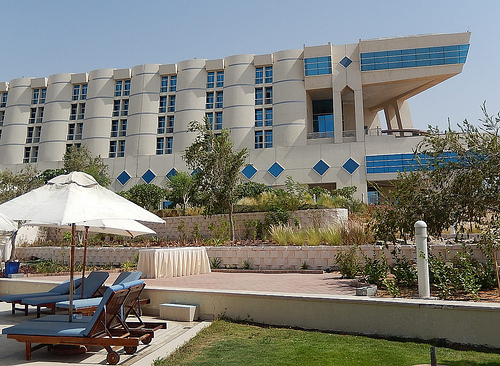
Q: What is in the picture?
A: A building.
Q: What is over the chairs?
A: An umbrella.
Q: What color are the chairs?
A: Blue.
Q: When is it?
A: Day time.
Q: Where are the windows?
A: On the building.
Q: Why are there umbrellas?
A: For shade.